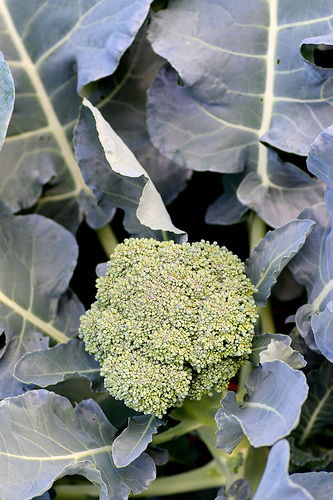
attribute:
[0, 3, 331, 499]
broccoli — starting to grow, green, light green, fresh looking, vegetable, existing, rough looking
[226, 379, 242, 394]
line — red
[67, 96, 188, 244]
leaf — curling, blue, healthy looking, existing, purple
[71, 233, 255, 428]
floret — tight, green, yellow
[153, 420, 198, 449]
stalk — existing